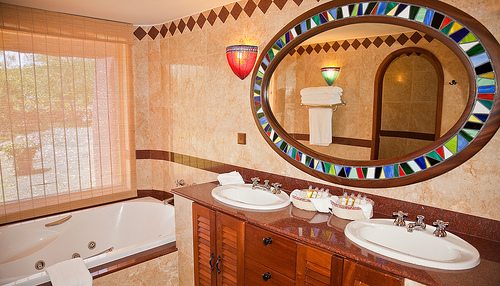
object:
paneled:
[169, 166, 500, 286]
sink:
[356, 223, 473, 264]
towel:
[40, 257, 97, 286]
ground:
[381, 202, 391, 214]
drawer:
[240, 221, 297, 280]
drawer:
[241, 258, 298, 286]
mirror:
[243, 0, 498, 191]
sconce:
[224, 44, 259, 81]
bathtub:
[0, 195, 175, 286]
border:
[136, 149, 500, 244]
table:
[169, 177, 500, 286]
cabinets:
[189, 199, 347, 286]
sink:
[217, 186, 286, 206]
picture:
[0, 0, 500, 286]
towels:
[309, 108, 333, 146]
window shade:
[0, 1, 138, 229]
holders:
[300, 101, 346, 112]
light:
[223, 44, 259, 80]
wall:
[132, 0, 499, 240]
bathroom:
[1, 0, 498, 286]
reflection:
[256, 16, 479, 167]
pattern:
[244, 0, 500, 182]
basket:
[289, 189, 334, 213]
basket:
[329, 195, 373, 219]